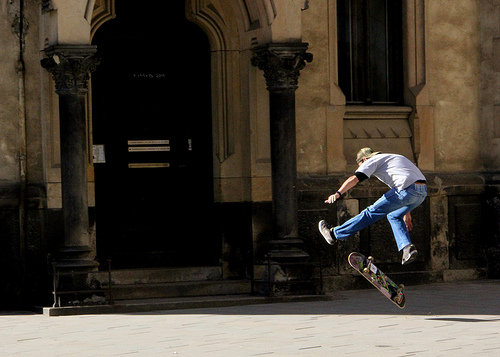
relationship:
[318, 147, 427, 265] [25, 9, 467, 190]
man in air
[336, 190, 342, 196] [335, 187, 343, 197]
black band on left wrist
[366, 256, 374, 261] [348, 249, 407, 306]
wheel on skateboard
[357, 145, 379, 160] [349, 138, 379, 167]
hat on head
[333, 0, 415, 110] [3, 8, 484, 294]
window on building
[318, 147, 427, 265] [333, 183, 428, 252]
man in blue jeans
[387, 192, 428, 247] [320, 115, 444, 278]
leg of person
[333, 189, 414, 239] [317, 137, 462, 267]
leg of person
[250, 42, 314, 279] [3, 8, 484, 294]
pillar on building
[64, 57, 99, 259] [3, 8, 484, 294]
pillar on building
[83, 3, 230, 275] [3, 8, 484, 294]
doorway on building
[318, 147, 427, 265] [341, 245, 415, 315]
man on skateboard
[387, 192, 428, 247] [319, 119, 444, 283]
leg on man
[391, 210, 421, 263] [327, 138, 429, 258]
leg on man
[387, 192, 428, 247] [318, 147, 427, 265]
leg on man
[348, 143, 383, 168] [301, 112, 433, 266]
head on man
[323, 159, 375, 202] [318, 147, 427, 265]
arm of a man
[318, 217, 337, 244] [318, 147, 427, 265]
foot of a man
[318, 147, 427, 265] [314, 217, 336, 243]
man wearing sneaker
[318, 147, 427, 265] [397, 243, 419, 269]
man wearing sneaker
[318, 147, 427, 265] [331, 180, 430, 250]
man wearing blue jeans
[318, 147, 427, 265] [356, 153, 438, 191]
man wearing shirt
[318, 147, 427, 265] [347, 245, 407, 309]
man in mid air on a skateboard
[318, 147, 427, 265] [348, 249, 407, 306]
man in mid air on a skateboard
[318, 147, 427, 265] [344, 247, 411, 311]
man in mid air on a skateboard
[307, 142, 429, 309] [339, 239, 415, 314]
man on skateboard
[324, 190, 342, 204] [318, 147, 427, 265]
hand on man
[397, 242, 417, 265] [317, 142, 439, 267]
foot on person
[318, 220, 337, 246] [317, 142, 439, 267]
foot on person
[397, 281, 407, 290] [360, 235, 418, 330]
wheel on skateboard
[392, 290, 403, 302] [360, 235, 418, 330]
wheel on skateboard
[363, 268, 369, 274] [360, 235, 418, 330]
wheel on skateboard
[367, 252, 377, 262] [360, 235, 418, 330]
wheel on skateboard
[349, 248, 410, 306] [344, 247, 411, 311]
bottom of skateboard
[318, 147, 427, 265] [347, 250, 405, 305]
man jumping up on skate board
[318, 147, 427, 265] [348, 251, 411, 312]
man on skateboard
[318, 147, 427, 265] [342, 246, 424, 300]
man on skateboard